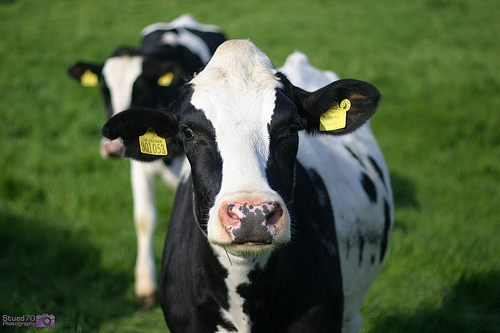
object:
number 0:
[29, 313, 37, 321]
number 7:
[24, 312, 31, 322]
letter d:
[18, 312, 26, 321]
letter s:
[0, 313, 8, 324]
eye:
[180, 123, 197, 141]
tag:
[79, 68, 99, 88]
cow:
[64, 12, 229, 311]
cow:
[99, 35, 393, 333]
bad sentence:
[432, 269, 445, 281]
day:
[0, 0, 499, 332]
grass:
[2, 1, 67, 195]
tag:
[154, 70, 175, 87]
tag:
[136, 125, 169, 156]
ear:
[99, 103, 182, 166]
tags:
[315, 102, 358, 133]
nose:
[215, 198, 285, 235]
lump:
[200, 38, 276, 76]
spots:
[343, 147, 396, 268]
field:
[0, 0, 499, 332]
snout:
[160, 52, 399, 332]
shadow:
[0, 171, 168, 333]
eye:
[276, 124, 298, 149]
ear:
[302, 79, 385, 139]